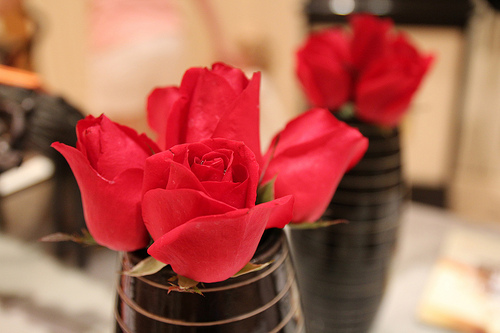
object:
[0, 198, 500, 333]
table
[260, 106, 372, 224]
flower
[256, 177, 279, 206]
stem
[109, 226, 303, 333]
vase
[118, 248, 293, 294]
lines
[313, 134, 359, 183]
petal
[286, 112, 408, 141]
groove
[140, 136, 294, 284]
flower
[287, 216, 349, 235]
leaf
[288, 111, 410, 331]
vase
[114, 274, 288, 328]
lines